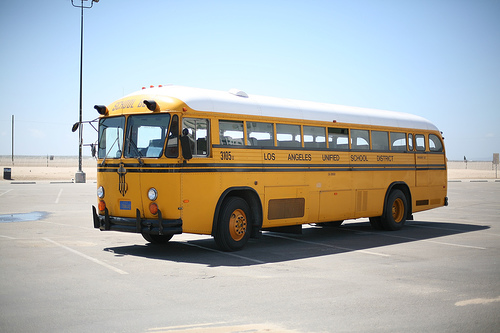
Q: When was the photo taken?
A: During the day.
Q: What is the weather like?
A: Sunny and clear.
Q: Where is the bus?
A: Parking lot.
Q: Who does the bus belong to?
A: Los Angeles Unified School District.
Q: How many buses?
A: One.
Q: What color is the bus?
A: Yellow.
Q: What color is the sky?
A: Blue.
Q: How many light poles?
A: One light pole.